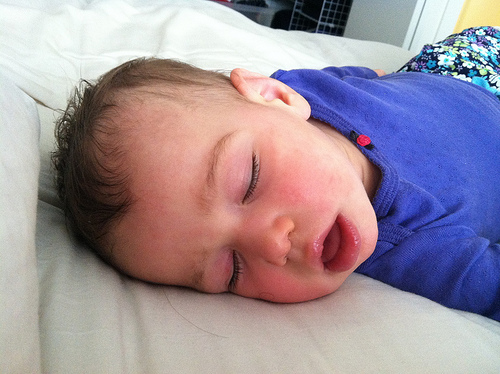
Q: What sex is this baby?
A: Girl.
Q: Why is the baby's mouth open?
A: Breathing.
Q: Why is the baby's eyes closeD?
A: She is sleeping.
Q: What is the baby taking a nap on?
A: Parent's bed.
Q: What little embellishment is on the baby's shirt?
A: Pink flower.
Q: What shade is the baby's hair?
A: Brown.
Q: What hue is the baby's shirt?
A: Royal blue.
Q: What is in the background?
A: Closet.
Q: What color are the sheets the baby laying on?
A: White.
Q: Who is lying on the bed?
A: A baby.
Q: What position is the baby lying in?
A: On its back.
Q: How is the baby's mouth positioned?
A: It's open.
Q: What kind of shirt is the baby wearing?
A: A blue t-shirt.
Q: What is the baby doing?
A: Sleeping.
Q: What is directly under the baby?
A: A white sheet.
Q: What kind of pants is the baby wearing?
A: Blue floral print.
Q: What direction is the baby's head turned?
A: To the right.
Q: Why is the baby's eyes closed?
A: She is asleep.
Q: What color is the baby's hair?
A: Brown.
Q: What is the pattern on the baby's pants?
A: Floral.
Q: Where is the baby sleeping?
A: Bed.